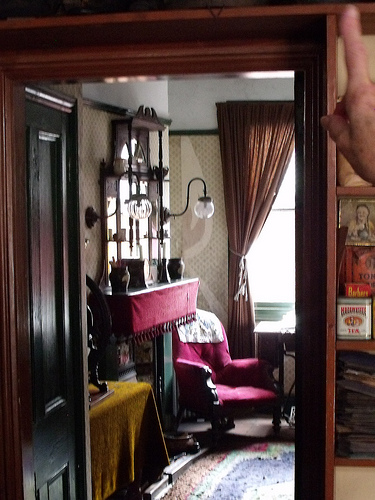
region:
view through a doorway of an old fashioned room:
[11, 10, 335, 498]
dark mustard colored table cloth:
[88, 379, 168, 499]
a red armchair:
[173, 308, 286, 438]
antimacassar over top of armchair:
[176, 306, 224, 344]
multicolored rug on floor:
[166, 439, 295, 499]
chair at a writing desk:
[252, 318, 294, 426]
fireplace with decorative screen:
[106, 313, 194, 457]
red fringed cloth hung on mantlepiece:
[99, 277, 200, 342]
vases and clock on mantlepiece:
[102, 256, 190, 294]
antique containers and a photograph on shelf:
[334, 189, 373, 339]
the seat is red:
[179, 333, 280, 412]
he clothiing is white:
[199, 308, 223, 338]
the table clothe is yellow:
[95, 386, 175, 484]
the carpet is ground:
[209, 450, 289, 496]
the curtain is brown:
[227, 153, 258, 329]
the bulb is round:
[193, 187, 231, 220]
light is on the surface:
[229, 454, 286, 499]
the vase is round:
[162, 253, 198, 277]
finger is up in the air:
[339, 9, 372, 155]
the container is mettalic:
[342, 299, 374, 343]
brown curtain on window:
[215, 99, 300, 357]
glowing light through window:
[243, 124, 298, 303]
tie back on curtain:
[229, 247, 252, 354]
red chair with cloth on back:
[174, 308, 279, 433]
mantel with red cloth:
[107, 277, 200, 345]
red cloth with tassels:
[122, 281, 200, 344]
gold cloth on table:
[91, 380, 169, 498]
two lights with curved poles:
[86, 171, 214, 228]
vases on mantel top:
[103, 256, 195, 296]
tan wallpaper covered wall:
[84, 97, 229, 345]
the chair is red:
[172, 307, 264, 424]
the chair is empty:
[161, 300, 281, 447]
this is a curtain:
[220, 98, 265, 240]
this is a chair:
[199, 339, 244, 415]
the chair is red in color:
[222, 369, 257, 421]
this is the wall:
[176, 91, 219, 128]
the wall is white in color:
[171, 85, 204, 116]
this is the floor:
[224, 465, 252, 493]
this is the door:
[9, 222, 72, 454]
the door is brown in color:
[15, 221, 60, 351]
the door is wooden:
[16, 156, 51, 277]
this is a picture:
[344, 200, 373, 237]